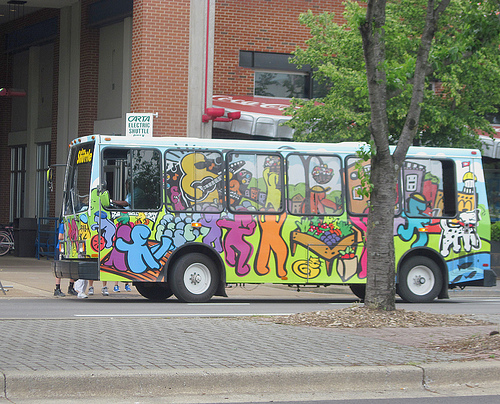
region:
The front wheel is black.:
[164, 252, 224, 301]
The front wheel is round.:
[169, 253, 219, 302]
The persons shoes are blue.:
[111, 283, 133, 290]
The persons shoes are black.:
[56, 285, 78, 296]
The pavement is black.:
[17, 297, 67, 317]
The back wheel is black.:
[400, 253, 444, 301]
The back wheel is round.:
[399, 253, 444, 299]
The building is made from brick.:
[148, 36, 180, 93]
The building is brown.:
[150, 13, 181, 95]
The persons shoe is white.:
[78, 288, 86, 300]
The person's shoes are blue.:
[113, 282, 130, 291]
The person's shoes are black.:
[53, 283, 77, 297]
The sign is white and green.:
[123, 113, 152, 135]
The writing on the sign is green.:
[125, 111, 154, 136]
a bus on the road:
[42, 16, 421, 393]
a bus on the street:
[60, 66, 493, 366]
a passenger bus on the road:
[69, 66, 420, 325]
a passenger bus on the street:
[54, 81, 464, 366]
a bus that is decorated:
[37, 97, 408, 366]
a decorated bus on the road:
[77, 89, 440, 375]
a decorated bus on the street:
[49, 76, 354, 400]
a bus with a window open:
[61, 119, 232, 276]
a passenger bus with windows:
[44, 105, 311, 336]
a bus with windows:
[57, 131, 229, 325]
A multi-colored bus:
[46, 116, 496, 311]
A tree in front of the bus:
[283, 2, 496, 325]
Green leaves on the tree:
[286, 2, 499, 150]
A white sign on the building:
[123, 112, 159, 135]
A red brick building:
[0, 0, 498, 267]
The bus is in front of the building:
[50, 129, 497, 307]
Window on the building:
[253, 67, 308, 104]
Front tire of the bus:
[166, 248, 229, 303]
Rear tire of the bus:
[395, 246, 450, 311]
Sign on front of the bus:
[67, 142, 94, 167]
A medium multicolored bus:
[56, 133, 489, 303]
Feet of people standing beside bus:
[55, 275, 133, 298]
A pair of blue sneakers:
[114, 283, 130, 292]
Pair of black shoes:
[52, 281, 74, 298]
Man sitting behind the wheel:
[106, 178, 143, 208]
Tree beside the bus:
[282, 10, 497, 311]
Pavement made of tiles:
[0, 321, 452, 371]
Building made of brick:
[51, 10, 346, 150]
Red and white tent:
[212, 90, 498, 150]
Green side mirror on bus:
[102, 187, 114, 209]